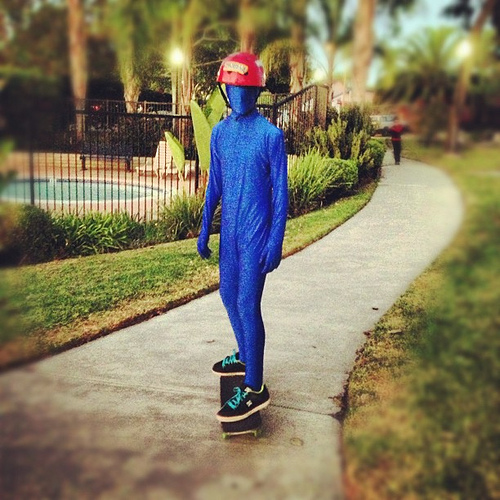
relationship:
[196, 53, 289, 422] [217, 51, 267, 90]
man wearing helmet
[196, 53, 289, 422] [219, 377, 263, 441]
man on skateboard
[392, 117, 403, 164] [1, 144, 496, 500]
man on ground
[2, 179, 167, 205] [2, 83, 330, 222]
pool behind fence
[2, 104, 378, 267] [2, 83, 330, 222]
bushes are beside fence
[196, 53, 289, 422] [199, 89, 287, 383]
man wearing bodysuit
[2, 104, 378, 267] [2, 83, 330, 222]
bushes are along fence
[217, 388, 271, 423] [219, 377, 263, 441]
foot on skateboard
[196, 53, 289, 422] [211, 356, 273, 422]
man wearing shoes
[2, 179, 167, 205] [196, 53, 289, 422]
pool behind man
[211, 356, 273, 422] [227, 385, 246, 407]
shoes have laces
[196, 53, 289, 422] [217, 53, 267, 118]
man has head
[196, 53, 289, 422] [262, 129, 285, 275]
man has arm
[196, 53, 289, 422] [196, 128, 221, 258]
man has arm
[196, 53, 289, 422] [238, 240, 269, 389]
man has leg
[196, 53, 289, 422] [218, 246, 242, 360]
man has leg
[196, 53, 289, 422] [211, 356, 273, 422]
man has shoes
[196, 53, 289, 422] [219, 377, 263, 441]
man has skateboard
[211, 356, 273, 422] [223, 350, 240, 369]
shoes have laces